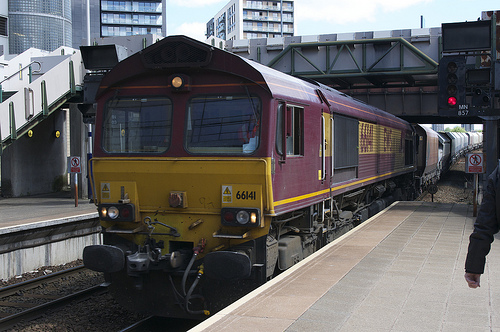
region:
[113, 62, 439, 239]
The train on the track.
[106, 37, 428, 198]
The train is yellow and red.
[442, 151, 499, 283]
A person arm on the platform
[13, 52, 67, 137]
Stairs to walkway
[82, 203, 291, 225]
The headlights in front of the train.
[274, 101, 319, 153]
Window on the train.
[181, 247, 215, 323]
Cords hanging in front of the train.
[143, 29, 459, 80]
Walkway above the train.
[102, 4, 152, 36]
Windos on the building.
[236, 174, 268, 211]
Black numbrs on the train.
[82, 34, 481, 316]
the train on the track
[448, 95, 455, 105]
the red light turned on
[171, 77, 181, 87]
the light on the train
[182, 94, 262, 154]
the windshield on the train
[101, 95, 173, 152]
the windshield on the train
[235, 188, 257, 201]
the numbers on the front of the train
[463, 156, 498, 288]
the arm of a person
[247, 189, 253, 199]
the number 4 on the train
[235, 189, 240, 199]
the number 6 on the train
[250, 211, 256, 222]
the light on the train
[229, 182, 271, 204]
black numbers on front of train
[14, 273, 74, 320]
brown metal train tracks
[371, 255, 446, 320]
grey stone tiles on train platform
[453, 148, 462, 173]
metal warning sign on platform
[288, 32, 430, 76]
green metal bars above train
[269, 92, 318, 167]
window on side of train engine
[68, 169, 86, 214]
white and orange sign post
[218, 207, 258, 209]
lights on front of train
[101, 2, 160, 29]
row of windows on side of building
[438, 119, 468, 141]
tree with green leaves behind train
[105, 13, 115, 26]
window of a building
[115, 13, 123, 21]
window of a building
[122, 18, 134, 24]
window of a building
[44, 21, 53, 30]
window of a building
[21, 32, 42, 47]
window of a building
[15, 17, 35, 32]
window of a building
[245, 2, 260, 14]
window of a building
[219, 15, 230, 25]
window of a building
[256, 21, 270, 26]
window of a building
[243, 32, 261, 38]
window of a building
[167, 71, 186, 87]
one round illuminated train headlight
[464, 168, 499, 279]
left dark long sleeve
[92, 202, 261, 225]
two round shiny train headlights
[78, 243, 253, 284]
two black metal stop pieces on front of train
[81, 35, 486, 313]
one long train at platform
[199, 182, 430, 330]
broad yellow section of train platform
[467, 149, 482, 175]
one red and white street sign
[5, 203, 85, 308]
edge of concrete train platform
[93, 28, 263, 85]
arched black metal top of train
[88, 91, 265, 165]
two front rectangular train windows